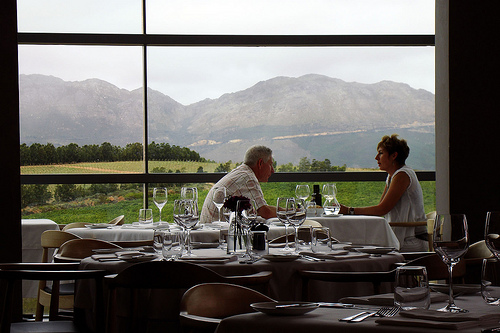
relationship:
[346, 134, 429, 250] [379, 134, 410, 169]
woman has hair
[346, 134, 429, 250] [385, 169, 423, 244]
woman wearing shirt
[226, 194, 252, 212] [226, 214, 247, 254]
flower in vase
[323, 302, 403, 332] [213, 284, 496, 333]
silverware on table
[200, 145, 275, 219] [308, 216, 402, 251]
man at table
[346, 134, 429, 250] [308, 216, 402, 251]
woman at table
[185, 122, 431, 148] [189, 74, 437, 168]
road on mountain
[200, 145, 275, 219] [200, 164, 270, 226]
man wearing shirt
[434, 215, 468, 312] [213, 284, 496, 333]
glass on table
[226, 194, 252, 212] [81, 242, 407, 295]
flower on table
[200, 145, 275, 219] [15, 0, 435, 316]
man in front of window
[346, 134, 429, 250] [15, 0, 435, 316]
woman in front of window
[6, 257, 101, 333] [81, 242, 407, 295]
seat at table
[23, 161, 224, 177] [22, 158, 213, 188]
crops in field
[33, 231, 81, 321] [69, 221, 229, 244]
chair at table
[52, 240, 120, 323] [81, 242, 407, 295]
chair at table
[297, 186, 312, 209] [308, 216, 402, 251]
glass on table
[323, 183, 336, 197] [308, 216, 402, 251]
glass on table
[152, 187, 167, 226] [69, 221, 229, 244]
glass on table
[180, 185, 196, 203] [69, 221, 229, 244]
glass on table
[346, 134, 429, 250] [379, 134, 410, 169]
woman with hair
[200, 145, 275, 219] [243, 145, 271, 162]
man with hair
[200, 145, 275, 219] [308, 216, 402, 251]
man over table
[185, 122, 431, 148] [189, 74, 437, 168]
road leading up mountain